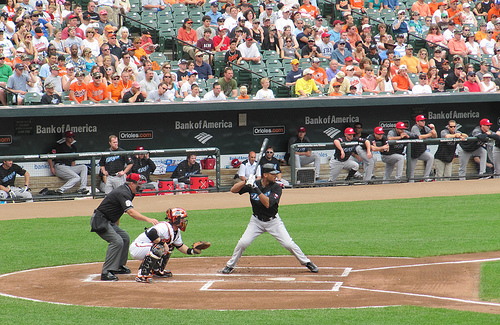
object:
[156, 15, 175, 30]
empty seats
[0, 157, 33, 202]
player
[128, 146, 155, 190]
player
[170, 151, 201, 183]
player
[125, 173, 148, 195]
mask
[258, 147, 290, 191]
man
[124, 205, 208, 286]
catcher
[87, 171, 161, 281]
umpire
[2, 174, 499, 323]
field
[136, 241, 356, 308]
lines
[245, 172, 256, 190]
white glove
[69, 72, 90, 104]
person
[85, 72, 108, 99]
person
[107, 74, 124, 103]
person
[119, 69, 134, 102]
person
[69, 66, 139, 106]
row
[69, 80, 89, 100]
shirt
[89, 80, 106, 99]
shirt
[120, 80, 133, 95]
shirt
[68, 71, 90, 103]
men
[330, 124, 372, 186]
man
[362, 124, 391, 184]
man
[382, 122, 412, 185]
man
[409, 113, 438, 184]
man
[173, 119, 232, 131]
letters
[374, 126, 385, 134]
ball cap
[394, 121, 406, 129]
ball cap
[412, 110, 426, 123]
ball cap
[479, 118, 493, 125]
ball cap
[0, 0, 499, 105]
crowd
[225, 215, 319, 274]
pants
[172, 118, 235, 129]
sign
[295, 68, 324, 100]
people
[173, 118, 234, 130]
logo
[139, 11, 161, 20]
seats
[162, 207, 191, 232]
mask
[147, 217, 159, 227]
hand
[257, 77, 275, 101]
people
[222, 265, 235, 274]
right foot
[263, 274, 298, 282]
base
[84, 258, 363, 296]
home plate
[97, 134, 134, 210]
player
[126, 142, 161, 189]
player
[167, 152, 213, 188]
player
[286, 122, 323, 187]
player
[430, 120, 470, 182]
player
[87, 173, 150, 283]
man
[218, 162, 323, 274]
batter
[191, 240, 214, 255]
glove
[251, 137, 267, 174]
bat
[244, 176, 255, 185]
hand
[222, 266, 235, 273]
foot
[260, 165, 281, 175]
helmet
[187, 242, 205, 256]
hand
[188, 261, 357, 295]
dirt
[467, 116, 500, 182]
player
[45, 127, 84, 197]
player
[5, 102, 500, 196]
dugout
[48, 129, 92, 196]
player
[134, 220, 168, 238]
back